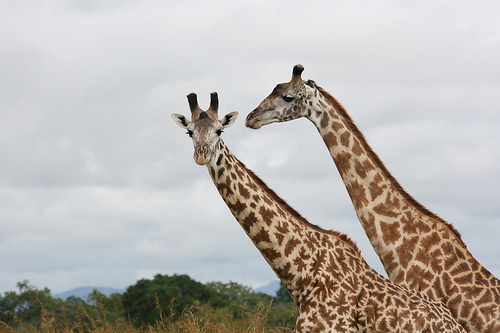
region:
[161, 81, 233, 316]
tan and brown spotted giraffe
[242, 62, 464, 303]
tan and brown spotted giraffe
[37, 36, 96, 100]
white clouds in blue sky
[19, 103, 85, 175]
white clouds in blue sky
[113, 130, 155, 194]
white clouds in blue sky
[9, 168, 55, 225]
white clouds in blue sky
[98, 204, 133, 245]
white clouds in blue sky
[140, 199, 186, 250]
white clouds in blue sky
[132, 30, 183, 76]
white clouds in blue sky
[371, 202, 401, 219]
brown spot on giraffe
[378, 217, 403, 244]
brown spot on giraffe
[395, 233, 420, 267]
brown spot on giraffe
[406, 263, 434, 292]
brown spot on giraffe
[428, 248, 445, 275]
brown spot on giraffe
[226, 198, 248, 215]
brown spot on giraffe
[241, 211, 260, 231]
brown spot on giraffe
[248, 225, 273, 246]
brown spot on giraffe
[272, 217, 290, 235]
brown spot on giraffe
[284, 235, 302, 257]
brown spot on giraffe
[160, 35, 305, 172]
the head of a giraffe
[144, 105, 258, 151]
the ears of a giraffe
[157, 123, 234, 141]
the eyes of a giraffe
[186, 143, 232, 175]
the nose of a giraffe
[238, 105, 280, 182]
the mouth of a giraffe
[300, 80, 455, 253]
the neck of a giraffe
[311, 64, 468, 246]
the main of a giraffe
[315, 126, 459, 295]
a brown spotted giraffe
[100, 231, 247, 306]
green trees in the background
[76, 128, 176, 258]
clouds in a sky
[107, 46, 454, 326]
giraffes walking outside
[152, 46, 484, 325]
giraffes standing outside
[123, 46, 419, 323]
two giraffes standing outside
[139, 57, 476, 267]
two giraffes standing up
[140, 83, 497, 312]
two tall giraffes outside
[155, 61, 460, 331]
two tall giraffes standing up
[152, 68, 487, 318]
giraffes with long necks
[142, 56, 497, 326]
two giraffes with long necks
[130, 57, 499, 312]
two long neck giraffes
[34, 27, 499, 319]
a sky with clouds